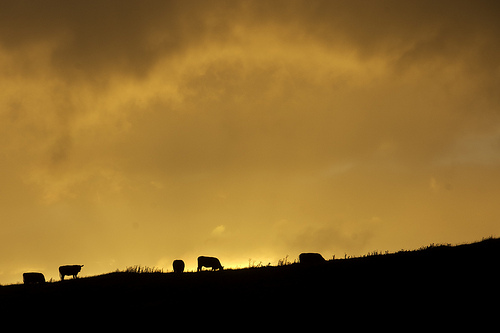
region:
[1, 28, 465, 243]
the sky is overcast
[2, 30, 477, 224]
the sky is golden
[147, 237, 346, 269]
animals on the hill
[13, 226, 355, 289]
animals are in shadow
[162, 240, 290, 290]
the sun is going down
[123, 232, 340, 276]
the cows are grazing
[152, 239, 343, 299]
3 cows are eating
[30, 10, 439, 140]
the clouds are dark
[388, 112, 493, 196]
the sky is peeking through the clouds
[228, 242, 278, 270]
the sun is bright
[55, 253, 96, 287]
cow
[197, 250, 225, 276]
cow grazing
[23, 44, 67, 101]
white clouds in yellow sky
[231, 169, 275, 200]
white clouds in yellow sky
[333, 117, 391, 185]
white clouds in yellow sky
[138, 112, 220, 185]
white clouds in yellow sky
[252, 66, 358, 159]
white clouds in yellow sky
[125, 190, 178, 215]
white clouds in yellow sky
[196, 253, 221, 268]
Cow grazing in field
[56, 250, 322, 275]
Three cows standing on hillside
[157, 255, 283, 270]
Sun setting in the distance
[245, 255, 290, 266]
Plants growing on the hillside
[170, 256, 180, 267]
Cow facing toward the sun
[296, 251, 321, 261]
Cow walking over the hill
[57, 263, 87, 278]
Cow standing on the hill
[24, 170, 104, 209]
White clouds in the sky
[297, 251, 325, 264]
First cow on the hill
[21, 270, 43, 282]
Last cow on the hill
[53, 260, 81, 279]
cow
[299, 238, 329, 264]
cow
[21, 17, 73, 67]
white clouds in yellow sky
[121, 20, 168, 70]
white clouds in yellow sky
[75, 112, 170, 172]
white clouds in yellow sky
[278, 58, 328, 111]
white clouds in yellow sky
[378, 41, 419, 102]
white clouds in yellow sky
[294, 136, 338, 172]
white clouds in yellow sky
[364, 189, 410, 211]
white clouds in yellow sky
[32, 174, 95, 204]
white clouds in yellow sky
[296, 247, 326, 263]
first animal on a slight hill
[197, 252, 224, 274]
2nd animal walking up a slight hill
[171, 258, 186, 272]
Third animal walking up a slight hill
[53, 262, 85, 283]
Fourth animal walking up a hill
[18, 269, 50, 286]
fifth animal walking up a hill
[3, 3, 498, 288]
cloudy yellow sky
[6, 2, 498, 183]
large cloud in the sky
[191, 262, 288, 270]
sun setting across the country side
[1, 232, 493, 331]
hill the animals are on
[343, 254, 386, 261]
grass growing on the hill